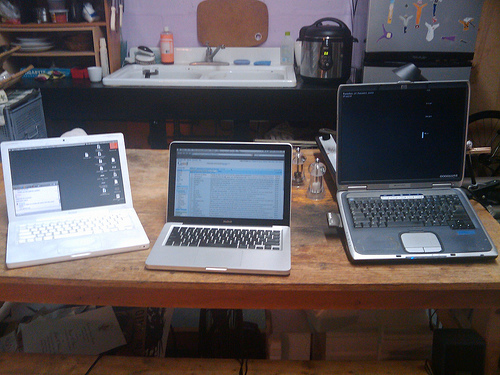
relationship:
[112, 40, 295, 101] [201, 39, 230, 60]
white double sink under faucet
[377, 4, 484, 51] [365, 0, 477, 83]
magnets on silver refrigerator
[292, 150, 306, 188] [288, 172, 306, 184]
shaker has pepper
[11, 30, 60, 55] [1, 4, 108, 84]
white dishes on shelf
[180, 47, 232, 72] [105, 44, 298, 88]
dish soap sitting on sink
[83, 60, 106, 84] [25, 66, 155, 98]
white cup sitting on counter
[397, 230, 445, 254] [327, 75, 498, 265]
touch pad on laptop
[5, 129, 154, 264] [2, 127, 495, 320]
laptop on surface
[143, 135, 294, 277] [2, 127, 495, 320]
laptop on surface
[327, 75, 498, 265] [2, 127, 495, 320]
laptop on surface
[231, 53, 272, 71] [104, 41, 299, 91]
soap on sink